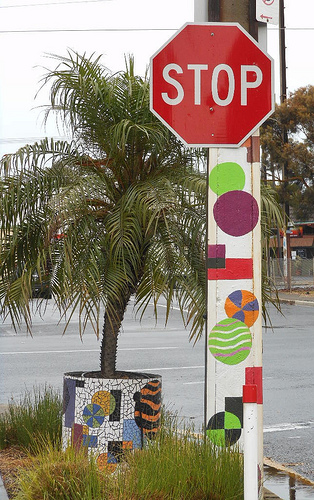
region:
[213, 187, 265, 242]
a circle on a post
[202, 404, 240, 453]
a circle on a post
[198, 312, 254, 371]
a circle on a post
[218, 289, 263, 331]
a circle on a post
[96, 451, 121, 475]
a circle on a post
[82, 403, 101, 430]
a circle on a post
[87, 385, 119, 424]
a circle on a post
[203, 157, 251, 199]
a circle on a post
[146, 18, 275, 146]
this is a sign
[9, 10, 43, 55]
this is the sky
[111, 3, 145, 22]
the sky is bright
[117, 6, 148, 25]
the sky is full of clouds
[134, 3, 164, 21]
the clouds are white in color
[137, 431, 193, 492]
this is the grass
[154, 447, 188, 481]
the grass is green in color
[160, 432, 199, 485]
the grass is tall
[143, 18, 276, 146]
this is a stop sign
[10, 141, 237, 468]
this is a tree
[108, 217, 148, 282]
the leaves are green in color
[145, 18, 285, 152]
stop sign on post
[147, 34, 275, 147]
red and white sign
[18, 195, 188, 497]
palm tree in pot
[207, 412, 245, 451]
green and black circle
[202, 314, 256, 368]
purple and white stripes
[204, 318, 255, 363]
green circle with stripes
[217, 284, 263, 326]
orange and purple circle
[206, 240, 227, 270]
purple and black square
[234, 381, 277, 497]
white pole with red top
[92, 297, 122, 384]
spines on tree trunk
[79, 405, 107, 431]
this is a design on sign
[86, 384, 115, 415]
this is a design on sign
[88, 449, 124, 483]
this is a design on sign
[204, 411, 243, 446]
this is a design on sign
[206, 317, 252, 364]
this is a design on sign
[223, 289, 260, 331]
this is a design on sign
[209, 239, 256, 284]
this is a design on sign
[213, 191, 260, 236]
this is a design on sign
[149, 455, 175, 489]
part of a grass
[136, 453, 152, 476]
part of a grass